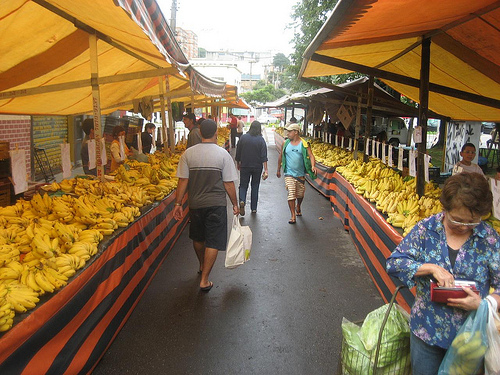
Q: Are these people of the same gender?
A: No, they are both male and female.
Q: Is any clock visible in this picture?
A: No, there are no clocks.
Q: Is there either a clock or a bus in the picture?
A: No, there are no clocks or buses.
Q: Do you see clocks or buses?
A: No, there are no clocks or buses.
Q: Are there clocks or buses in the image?
A: No, there are no clocks or buses.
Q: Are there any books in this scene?
A: No, there are no books.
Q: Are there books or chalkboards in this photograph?
A: No, there are no books or chalkboards.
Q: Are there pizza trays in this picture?
A: No, there are no pizza trays.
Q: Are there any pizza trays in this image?
A: No, there are no pizza trays.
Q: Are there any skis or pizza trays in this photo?
A: No, there are no pizza trays or skis.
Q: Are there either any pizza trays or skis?
A: No, there are no pizza trays or skis.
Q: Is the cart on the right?
A: Yes, the cart is on the right of the image.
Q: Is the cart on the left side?
A: No, the cart is on the right of the image.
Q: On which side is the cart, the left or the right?
A: The cart is on the right of the image.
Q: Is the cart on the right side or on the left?
A: The cart is on the right of the image.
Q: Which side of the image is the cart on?
A: The cart is on the right of the image.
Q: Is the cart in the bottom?
A: Yes, the cart is in the bottom of the image.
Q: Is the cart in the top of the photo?
A: No, the cart is in the bottom of the image.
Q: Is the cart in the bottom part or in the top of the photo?
A: The cart is in the bottom of the image.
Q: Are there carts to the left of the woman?
A: Yes, there is a cart to the left of the woman.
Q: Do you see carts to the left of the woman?
A: Yes, there is a cart to the left of the woman.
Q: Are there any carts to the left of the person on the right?
A: Yes, there is a cart to the left of the woman.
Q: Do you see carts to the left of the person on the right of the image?
A: Yes, there is a cart to the left of the woman.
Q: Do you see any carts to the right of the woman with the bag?
A: No, the cart is to the left of the woman.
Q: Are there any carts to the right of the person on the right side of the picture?
A: No, the cart is to the left of the woman.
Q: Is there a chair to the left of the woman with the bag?
A: No, there is a cart to the left of the woman.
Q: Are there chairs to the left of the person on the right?
A: No, there is a cart to the left of the woman.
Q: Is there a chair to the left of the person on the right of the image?
A: No, there is a cart to the left of the woman.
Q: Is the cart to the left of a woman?
A: Yes, the cart is to the left of a woman.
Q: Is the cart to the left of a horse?
A: No, the cart is to the left of a woman.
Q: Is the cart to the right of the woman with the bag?
A: No, the cart is to the left of the woman.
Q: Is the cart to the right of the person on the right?
A: No, the cart is to the left of the woman.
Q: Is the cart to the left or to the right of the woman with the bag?
A: The cart is to the left of the woman.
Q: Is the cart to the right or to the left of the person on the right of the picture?
A: The cart is to the left of the woman.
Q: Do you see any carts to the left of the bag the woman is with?
A: Yes, there is a cart to the left of the bag.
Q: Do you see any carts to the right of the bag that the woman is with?
A: No, the cart is to the left of the bag.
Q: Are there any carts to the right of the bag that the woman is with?
A: No, the cart is to the left of the bag.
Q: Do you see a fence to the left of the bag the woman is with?
A: No, there is a cart to the left of the bag.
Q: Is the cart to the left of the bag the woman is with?
A: Yes, the cart is to the left of the bag.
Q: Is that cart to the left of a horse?
A: No, the cart is to the left of the bag.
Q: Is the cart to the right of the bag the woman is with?
A: No, the cart is to the left of the bag.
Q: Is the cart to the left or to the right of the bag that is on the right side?
A: The cart is to the left of the bag.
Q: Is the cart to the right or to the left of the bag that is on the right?
A: The cart is to the left of the bag.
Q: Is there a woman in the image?
A: Yes, there is a woman.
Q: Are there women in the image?
A: Yes, there is a woman.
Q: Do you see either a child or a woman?
A: Yes, there is a woman.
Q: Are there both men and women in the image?
A: Yes, there are both a woman and a man.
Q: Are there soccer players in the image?
A: No, there are no soccer players.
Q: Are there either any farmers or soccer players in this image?
A: No, there are no soccer players or farmers.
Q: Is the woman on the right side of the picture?
A: Yes, the woman is on the right of the image.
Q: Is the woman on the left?
A: No, the woman is on the right of the image.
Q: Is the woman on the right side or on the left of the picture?
A: The woman is on the right of the image.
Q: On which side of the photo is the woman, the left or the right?
A: The woman is on the right of the image.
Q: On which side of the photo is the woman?
A: The woman is on the right of the image.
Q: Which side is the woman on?
A: The woman is on the right of the image.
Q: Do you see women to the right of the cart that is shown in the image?
A: Yes, there is a woman to the right of the cart.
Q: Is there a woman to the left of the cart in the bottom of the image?
A: No, the woman is to the right of the cart.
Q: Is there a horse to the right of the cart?
A: No, there is a woman to the right of the cart.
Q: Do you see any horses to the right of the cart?
A: No, there is a woman to the right of the cart.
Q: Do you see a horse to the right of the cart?
A: No, there is a woman to the right of the cart.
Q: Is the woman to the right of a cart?
A: Yes, the woman is to the right of a cart.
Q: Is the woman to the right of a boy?
A: No, the woman is to the right of a cart.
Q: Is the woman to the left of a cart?
A: No, the woman is to the right of a cart.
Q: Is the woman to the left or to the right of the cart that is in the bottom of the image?
A: The woman is to the right of the cart.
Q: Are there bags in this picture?
A: Yes, there is a bag.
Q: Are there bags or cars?
A: Yes, there is a bag.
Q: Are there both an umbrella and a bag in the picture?
A: No, there is a bag but no umbrellas.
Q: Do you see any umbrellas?
A: No, there are no umbrellas.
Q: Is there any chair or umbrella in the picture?
A: No, there are no umbrellas or chairs.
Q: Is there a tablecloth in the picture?
A: Yes, there is a tablecloth.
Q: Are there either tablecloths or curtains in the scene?
A: Yes, there is a tablecloth.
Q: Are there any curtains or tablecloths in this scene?
A: Yes, there is a tablecloth.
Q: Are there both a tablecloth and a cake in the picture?
A: No, there is a tablecloth but no cakes.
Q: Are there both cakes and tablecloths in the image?
A: No, there is a tablecloth but no cakes.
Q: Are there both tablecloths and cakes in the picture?
A: No, there is a tablecloth but no cakes.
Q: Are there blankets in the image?
A: No, there are no blankets.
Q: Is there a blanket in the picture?
A: No, there are no blankets.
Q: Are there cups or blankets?
A: No, there are no blankets or cups.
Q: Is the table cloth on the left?
A: Yes, the table cloth is on the left of the image.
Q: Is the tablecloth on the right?
A: No, the tablecloth is on the left of the image.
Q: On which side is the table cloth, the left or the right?
A: The table cloth is on the left of the image.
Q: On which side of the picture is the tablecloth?
A: The tablecloth is on the left of the image.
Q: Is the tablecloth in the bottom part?
A: Yes, the tablecloth is in the bottom of the image.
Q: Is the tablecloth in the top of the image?
A: No, the tablecloth is in the bottom of the image.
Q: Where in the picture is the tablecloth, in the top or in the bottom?
A: The tablecloth is in the bottom of the image.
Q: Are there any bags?
A: Yes, there is a bag.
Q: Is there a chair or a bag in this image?
A: Yes, there is a bag.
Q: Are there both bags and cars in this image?
A: No, there is a bag but no cars.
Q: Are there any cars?
A: No, there are no cars.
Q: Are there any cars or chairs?
A: No, there are no cars or chairs.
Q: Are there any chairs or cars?
A: No, there are no cars or chairs.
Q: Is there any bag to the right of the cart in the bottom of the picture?
A: Yes, there is a bag to the right of the cart.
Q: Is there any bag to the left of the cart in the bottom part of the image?
A: No, the bag is to the right of the cart.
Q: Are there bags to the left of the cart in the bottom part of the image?
A: No, the bag is to the right of the cart.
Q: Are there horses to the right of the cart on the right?
A: No, there is a bag to the right of the cart.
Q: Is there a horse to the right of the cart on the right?
A: No, there is a bag to the right of the cart.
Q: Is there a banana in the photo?
A: Yes, there are bananas.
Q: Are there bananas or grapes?
A: Yes, there are bananas.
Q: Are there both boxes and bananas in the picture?
A: No, there are bananas but no boxes.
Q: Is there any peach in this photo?
A: No, there are no peaches.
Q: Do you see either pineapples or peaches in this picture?
A: No, there are no peaches or pineapples.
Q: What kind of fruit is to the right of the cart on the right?
A: The fruits are bananas.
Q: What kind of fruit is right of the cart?
A: The fruits are bananas.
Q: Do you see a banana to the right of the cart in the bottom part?
A: Yes, there are bananas to the right of the cart.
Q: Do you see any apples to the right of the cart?
A: No, there are bananas to the right of the cart.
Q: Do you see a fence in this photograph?
A: No, there are no fences.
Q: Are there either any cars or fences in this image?
A: No, there are no fences or cars.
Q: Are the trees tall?
A: Yes, the trees are tall.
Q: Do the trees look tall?
A: Yes, the trees are tall.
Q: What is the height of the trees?
A: The trees are tall.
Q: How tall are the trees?
A: The trees are tall.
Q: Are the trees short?
A: No, the trees are tall.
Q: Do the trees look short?
A: No, the trees are tall.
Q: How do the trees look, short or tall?
A: The trees are tall.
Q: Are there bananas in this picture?
A: Yes, there are bananas.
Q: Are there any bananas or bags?
A: Yes, there are bananas.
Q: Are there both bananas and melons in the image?
A: No, there are bananas but no melons.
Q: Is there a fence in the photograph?
A: No, there are no fences.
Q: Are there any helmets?
A: No, there are no helmets.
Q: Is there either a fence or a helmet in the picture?
A: No, there are no helmets or fences.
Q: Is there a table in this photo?
A: Yes, there is a table.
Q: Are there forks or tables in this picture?
A: Yes, there is a table.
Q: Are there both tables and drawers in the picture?
A: No, there is a table but no drawers.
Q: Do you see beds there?
A: No, there are no beds.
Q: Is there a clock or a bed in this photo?
A: No, there are no beds or clocks.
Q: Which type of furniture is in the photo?
A: The furniture is a table.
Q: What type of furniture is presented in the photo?
A: The furniture is a table.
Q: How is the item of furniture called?
A: The piece of furniture is a table.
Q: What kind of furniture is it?
A: The piece of furniture is a table.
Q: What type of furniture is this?
A: That is a table.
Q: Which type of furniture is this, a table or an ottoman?
A: That is a table.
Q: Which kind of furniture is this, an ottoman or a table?
A: That is a table.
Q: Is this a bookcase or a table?
A: This is a table.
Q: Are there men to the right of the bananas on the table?
A: Yes, there is a man to the right of the bananas.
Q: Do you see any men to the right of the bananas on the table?
A: Yes, there is a man to the right of the bananas.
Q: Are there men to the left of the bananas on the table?
A: No, the man is to the right of the bananas.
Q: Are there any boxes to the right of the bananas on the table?
A: No, there is a man to the right of the bananas.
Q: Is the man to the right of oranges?
A: No, the man is to the right of the bananas.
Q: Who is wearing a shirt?
A: The man is wearing a shirt.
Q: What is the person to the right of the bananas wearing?
A: The man is wearing a shirt.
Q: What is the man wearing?
A: The man is wearing a shirt.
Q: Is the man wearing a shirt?
A: Yes, the man is wearing a shirt.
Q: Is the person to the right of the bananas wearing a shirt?
A: Yes, the man is wearing a shirt.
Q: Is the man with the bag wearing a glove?
A: No, the man is wearing a shirt.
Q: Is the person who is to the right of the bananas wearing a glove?
A: No, the man is wearing a shirt.